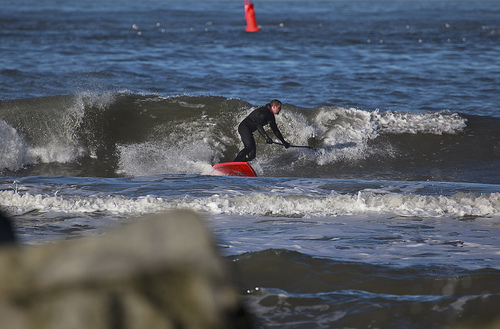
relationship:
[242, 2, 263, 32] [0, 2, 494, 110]
bouy in water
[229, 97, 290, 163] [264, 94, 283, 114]
surfer has head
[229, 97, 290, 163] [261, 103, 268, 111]
surfer has shoulder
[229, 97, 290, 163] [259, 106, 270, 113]
surfer has shoulder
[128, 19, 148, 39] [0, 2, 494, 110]
birds in water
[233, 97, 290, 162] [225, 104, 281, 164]
surfer in surfer suit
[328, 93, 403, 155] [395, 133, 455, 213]
cap on wave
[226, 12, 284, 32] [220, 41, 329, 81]
bouy in water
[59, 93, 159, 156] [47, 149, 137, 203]
curl in wave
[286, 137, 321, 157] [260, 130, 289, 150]
pole in hand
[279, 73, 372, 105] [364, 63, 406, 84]
ripples on surface